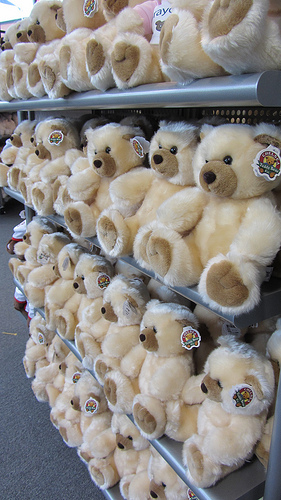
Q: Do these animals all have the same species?
A: Yes, all the animals are bears.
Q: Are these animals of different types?
A: No, all the animals are bears.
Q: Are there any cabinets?
A: No, there are no cabinets.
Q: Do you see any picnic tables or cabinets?
A: No, there are no cabinets or picnic tables.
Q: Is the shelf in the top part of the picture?
A: Yes, the shelf is in the top of the image.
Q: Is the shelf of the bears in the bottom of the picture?
A: No, the shelf is in the top of the image.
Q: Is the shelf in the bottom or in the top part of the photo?
A: The shelf is in the top of the image.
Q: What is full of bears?
A: The shelf is full of bears.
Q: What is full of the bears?
A: The shelf is full of bears.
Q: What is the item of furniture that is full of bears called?
A: The piece of furniture is a shelf.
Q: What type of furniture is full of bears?
A: The piece of furniture is a shelf.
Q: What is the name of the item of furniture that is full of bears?
A: The piece of furniture is a shelf.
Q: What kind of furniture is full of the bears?
A: The piece of furniture is a shelf.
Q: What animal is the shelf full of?
A: The shelf is full of bears.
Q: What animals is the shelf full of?
A: The shelf is full of bears.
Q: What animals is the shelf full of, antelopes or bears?
A: The shelf is full of bears.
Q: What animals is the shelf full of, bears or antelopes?
A: The shelf is full of bears.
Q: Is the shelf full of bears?
A: Yes, the shelf is full of bears.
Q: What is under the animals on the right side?
A: The shelf is under the bears.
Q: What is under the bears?
A: The shelf is under the bears.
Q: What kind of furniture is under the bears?
A: The piece of furniture is a shelf.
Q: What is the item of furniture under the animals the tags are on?
A: The piece of furniture is a shelf.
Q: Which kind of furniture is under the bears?
A: The piece of furniture is a shelf.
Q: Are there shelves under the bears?
A: Yes, there is a shelf under the bears.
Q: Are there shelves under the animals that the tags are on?
A: Yes, there is a shelf under the bears.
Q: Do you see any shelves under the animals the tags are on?
A: Yes, there is a shelf under the bears.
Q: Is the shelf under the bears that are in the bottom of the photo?
A: Yes, the shelf is under the bears.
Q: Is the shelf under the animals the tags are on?
A: Yes, the shelf is under the bears.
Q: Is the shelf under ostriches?
A: No, the shelf is under the bears.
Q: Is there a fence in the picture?
A: No, there are no fences.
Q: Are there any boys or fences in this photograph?
A: No, there are no fences or boys.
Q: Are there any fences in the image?
A: No, there are no fences.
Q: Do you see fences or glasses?
A: No, there are no fences or glasses.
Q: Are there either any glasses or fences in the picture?
A: No, there are no fences or glasses.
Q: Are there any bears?
A: Yes, there are bears.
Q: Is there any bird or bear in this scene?
A: Yes, there are bears.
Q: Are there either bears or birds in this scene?
A: Yes, there are bears.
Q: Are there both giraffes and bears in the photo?
A: No, there are bears but no giraffes.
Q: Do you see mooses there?
A: No, there are no mooses.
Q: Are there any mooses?
A: No, there are no mooses.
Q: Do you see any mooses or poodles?
A: No, there are no mooses or poodles.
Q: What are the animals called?
A: The animals are bears.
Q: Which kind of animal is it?
A: The animals are bears.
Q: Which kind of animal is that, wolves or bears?
A: These are bears.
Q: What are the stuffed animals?
A: The animals are bears.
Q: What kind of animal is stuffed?
A: The animal is bears.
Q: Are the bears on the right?
A: Yes, the bears are on the right of the image.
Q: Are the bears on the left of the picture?
A: No, the bears are on the right of the image.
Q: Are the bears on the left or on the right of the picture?
A: The bears are on the right of the image.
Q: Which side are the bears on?
A: The bears are on the right of the image.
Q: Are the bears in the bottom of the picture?
A: Yes, the bears are in the bottom of the image.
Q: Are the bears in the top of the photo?
A: No, the bears are in the bottom of the image.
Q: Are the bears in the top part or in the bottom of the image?
A: The bears are in the bottom of the image.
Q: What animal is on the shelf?
A: The bears are on the shelf.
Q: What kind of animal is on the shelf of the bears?
A: The animals are bears.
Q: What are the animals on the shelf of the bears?
A: The animals are bears.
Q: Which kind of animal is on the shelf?
A: The animals are bears.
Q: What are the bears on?
A: The bears are on the shelf.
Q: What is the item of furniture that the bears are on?
A: The piece of furniture is a shelf.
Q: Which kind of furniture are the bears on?
A: The bears are on the shelf.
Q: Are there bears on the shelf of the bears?
A: Yes, there are bears on the shelf.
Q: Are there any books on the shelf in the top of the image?
A: No, there are bears on the shelf.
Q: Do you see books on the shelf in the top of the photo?
A: No, there are bears on the shelf.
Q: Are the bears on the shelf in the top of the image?
A: Yes, the bears are on the shelf.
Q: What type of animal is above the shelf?
A: The animals are bears.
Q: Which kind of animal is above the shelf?
A: The animals are bears.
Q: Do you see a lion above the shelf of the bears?
A: No, there are bears above the shelf.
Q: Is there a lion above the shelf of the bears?
A: No, there are bears above the shelf.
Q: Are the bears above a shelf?
A: Yes, the bears are above a shelf.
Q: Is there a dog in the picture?
A: No, there are no dogs.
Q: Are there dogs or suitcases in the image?
A: No, there are no dogs or suitcases.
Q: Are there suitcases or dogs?
A: No, there are no dogs or suitcases.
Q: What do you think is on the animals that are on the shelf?
A: The tags are on the bears.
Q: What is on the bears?
A: The tags are on the bears.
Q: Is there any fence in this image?
A: No, there are no fences.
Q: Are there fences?
A: No, there are no fences.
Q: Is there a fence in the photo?
A: No, there are no fences.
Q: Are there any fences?
A: No, there are no fences.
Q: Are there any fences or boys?
A: No, there are no fences or boys.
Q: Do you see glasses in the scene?
A: No, there are no glasses.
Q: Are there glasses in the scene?
A: No, there are no glasses.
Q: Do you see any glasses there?
A: No, there are no glasses.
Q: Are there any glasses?
A: No, there are no glasses.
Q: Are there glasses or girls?
A: No, there are no glasses or girls.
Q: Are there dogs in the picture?
A: No, there are no dogs.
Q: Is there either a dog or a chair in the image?
A: No, there are no dogs or chairs.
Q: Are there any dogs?
A: No, there are no dogs.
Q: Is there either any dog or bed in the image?
A: No, there are no dogs or beds.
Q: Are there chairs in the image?
A: No, there are no chairs.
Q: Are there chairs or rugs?
A: No, there are no chairs or rugs.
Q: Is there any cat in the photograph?
A: No, there are no cats.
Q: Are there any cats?
A: No, there are no cats.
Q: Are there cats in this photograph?
A: No, there are no cats.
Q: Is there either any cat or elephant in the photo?
A: No, there are no cats or elephants.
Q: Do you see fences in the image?
A: No, there are no fences.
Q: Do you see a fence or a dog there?
A: No, there are no fences or dogs.